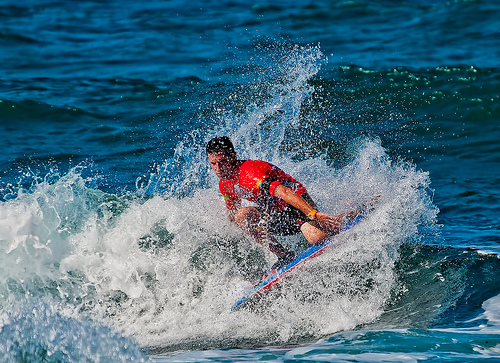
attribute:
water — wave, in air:
[0, 12, 447, 361]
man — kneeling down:
[187, 126, 385, 286]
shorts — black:
[251, 194, 311, 232]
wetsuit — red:
[215, 158, 320, 238]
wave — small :
[343, 128, 443, 196]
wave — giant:
[5, 179, 399, 355]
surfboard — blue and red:
[209, 181, 440, 326]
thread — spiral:
[253, 216, 277, 281]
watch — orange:
[306, 209, 318, 229]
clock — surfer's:
[303, 212, 313, 224]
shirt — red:
[209, 154, 298, 204]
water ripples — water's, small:
[22, 60, 166, 121]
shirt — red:
[218, 158, 307, 210]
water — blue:
[67, 22, 144, 62]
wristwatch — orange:
[304, 197, 341, 257]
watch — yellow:
[306, 208, 316, 221]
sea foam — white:
[7, 39, 212, 299]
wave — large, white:
[1, 40, 443, 342]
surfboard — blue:
[232, 192, 380, 319]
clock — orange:
[304, 205, 322, 221]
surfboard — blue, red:
[228, 198, 385, 298]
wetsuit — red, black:
[209, 155, 324, 240]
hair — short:
[205, 136, 236, 165]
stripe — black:
[259, 169, 278, 193]